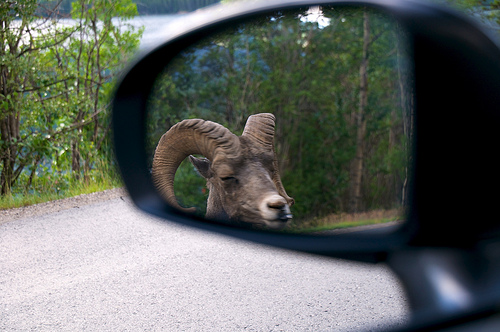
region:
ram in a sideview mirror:
[141, 90, 321, 242]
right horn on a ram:
[147, 113, 252, 213]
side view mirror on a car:
[94, 3, 498, 276]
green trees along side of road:
[4, 21, 101, 176]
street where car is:
[22, 214, 134, 319]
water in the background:
[127, 13, 174, 33]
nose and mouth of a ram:
[256, 193, 299, 228]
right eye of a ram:
[213, 166, 243, 189]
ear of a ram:
[179, 152, 216, 181]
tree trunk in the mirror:
[346, 11, 385, 218]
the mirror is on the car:
[100, 12, 482, 289]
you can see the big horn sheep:
[148, 91, 323, 241]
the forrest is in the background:
[147, 51, 409, 242]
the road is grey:
[21, 205, 261, 329]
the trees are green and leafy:
[4, 12, 104, 186]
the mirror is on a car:
[96, 24, 496, 320]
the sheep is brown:
[127, 104, 318, 244]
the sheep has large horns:
[115, 98, 305, 240]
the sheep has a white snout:
[121, 77, 335, 267]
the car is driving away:
[15, 14, 495, 310]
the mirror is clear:
[325, 193, 342, 222]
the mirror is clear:
[331, 186, 348, 200]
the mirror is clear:
[358, 209, 366, 224]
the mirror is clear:
[332, 183, 359, 218]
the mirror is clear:
[356, 186, 365, 197]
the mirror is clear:
[363, 192, 368, 204]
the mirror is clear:
[372, 150, 374, 168]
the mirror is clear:
[338, 160, 360, 205]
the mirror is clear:
[311, 222, 328, 237]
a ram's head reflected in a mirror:
[146, 100, 317, 242]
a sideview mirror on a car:
[103, 13, 481, 302]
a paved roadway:
[4, 185, 383, 330]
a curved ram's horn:
[149, 106, 239, 224]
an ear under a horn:
[188, 148, 224, 183]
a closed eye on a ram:
[220, 172, 241, 183]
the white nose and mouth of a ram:
[254, 187, 295, 232]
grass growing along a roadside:
[4, 171, 122, 209]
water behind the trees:
[9, 7, 171, 57]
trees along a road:
[0, 6, 133, 196]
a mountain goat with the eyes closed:
[143, 109, 295, 230]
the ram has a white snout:
[260, 190, 293, 228]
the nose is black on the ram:
[268, 200, 287, 216]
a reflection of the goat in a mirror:
[113, 7, 493, 257]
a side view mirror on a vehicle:
[107, 2, 499, 324]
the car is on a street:
[6, 188, 475, 330]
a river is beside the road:
[8, 5, 253, 280]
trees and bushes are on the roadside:
[5, 2, 497, 226]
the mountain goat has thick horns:
[150, 108, 297, 216]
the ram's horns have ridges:
[148, 107, 298, 224]